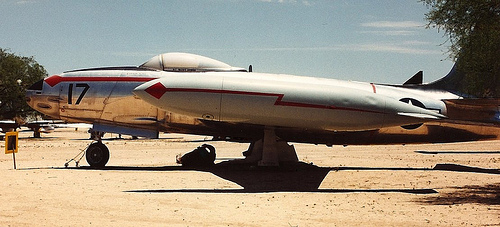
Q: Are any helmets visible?
A: No, there are no helmets.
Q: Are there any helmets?
A: No, there are no helmets.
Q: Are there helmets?
A: No, there are no helmets.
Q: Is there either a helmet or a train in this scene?
A: No, there are no helmets or trains.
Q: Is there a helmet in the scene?
A: No, there are no helmets.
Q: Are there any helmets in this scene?
A: No, there are no helmets.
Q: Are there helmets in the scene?
A: No, there are no helmets.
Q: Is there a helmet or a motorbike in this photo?
A: No, there are no helmets or motorcycles.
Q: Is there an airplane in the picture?
A: Yes, there is an airplane.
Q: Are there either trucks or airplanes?
A: Yes, there is an airplane.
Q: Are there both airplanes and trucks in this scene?
A: No, there is an airplane but no trucks.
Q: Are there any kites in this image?
A: No, there are no kites.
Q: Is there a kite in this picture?
A: No, there are no kites.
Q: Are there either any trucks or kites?
A: No, there are no kites or trucks.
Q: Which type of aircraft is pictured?
A: The aircraft is an airplane.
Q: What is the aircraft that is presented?
A: The aircraft is an airplane.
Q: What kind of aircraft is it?
A: The aircraft is an airplane.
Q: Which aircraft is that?
A: This is an airplane.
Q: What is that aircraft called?
A: This is an airplane.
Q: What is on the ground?
A: The airplane is on the ground.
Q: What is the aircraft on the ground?
A: The aircraft is an airplane.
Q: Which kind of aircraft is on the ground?
A: The aircraft is an airplane.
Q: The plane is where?
A: The plane is on the ground.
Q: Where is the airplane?
A: The plane is on the ground.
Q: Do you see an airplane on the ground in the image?
A: Yes, there is an airplane on the ground.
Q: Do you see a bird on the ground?
A: No, there is an airplane on the ground.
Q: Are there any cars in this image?
A: No, there are no cars.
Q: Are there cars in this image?
A: No, there are no cars.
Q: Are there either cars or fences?
A: No, there are no cars or fences.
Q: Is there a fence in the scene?
A: No, there are no fences.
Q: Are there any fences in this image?
A: No, there are no fences.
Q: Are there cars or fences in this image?
A: No, there are no fences or cars.